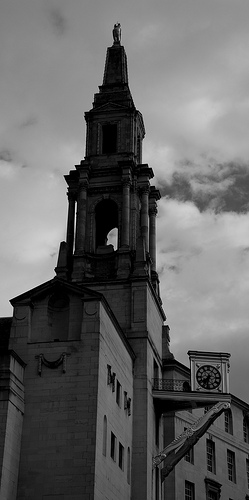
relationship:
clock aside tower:
[198, 363, 219, 388] [85, 23, 164, 496]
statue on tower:
[93, 29, 141, 54] [85, 23, 164, 496]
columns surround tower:
[65, 163, 143, 298] [85, 23, 164, 496]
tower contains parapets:
[85, 23, 164, 496] [93, 40, 141, 171]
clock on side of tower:
[198, 363, 219, 388] [85, 23, 164, 496]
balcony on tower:
[129, 373, 199, 407] [85, 23, 164, 496]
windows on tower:
[96, 377, 246, 486] [85, 23, 164, 496]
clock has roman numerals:
[198, 363, 219, 388] [196, 360, 220, 394]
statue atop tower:
[93, 29, 141, 54] [85, 23, 164, 496]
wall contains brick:
[17, 315, 126, 498] [20, 348, 99, 422]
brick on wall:
[20, 348, 99, 422] [17, 315, 126, 498]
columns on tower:
[65, 163, 143, 298] [85, 23, 164, 496]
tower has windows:
[85, 23, 164, 496] [96, 377, 246, 486]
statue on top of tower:
[93, 29, 141, 54] [85, 23, 164, 496]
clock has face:
[198, 363, 219, 388] [199, 367, 216, 382]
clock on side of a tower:
[198, 363, 219, 388] [85, 23, 164, 496]